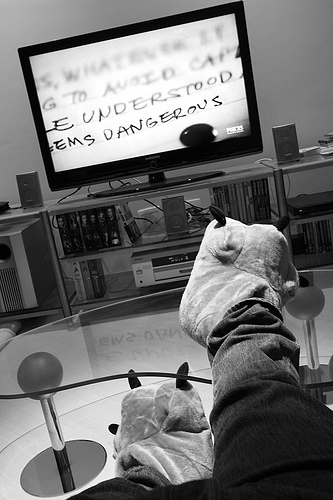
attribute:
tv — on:
[15, 3, 269, 199]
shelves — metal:
[0, 164, 327, 311]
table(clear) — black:
[0, 268, 332, 401]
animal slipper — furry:
[113, 395, 215, 487]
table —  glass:
[3, 267, 175, 382]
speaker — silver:
[1, 215, 56, 317]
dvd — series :
[210, 177, 274, 225]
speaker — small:
[15, 123, 299, 206]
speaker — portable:
[159, 194, 191, 239]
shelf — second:
[59, 211, 254, 263]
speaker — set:
[271, 123, 299, 165]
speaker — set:
[13, 171, 43, 209]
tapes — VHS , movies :
[52, 203, 124, 259]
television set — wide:
[16, 1, 262, 191]